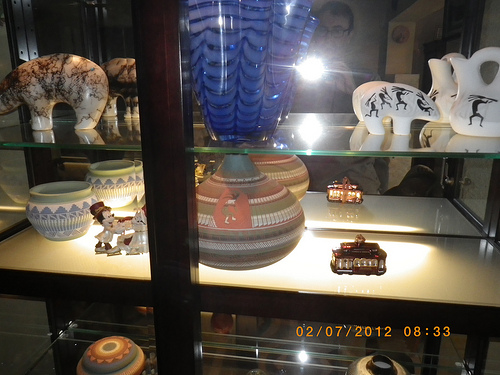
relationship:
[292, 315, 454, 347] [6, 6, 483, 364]
date of photo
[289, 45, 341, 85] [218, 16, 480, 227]
flash in mirror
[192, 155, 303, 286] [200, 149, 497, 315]
pottery in cabinet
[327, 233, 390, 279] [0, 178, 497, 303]
trolley toy on shelf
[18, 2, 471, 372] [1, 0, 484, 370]
wall supporting cabinet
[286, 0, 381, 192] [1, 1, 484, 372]
man reflected in glass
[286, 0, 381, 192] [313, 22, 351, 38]
man wearing glasses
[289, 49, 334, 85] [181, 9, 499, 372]
flash on glass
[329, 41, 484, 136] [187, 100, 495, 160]
items on shelf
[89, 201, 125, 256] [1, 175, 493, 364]
mickey mouse on hutch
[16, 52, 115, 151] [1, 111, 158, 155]
bear on hutch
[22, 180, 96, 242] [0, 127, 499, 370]
bowl on hutch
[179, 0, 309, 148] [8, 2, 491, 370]
glass on hutch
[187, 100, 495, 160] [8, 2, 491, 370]
shelf in hutch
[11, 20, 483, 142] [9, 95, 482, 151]
objects on shelf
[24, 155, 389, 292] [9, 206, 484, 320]
objects on shelf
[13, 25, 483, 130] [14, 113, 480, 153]
objects on shelf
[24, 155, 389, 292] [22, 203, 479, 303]
objects on shelf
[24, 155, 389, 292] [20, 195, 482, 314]
objects on shelf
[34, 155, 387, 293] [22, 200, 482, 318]
objects on shlef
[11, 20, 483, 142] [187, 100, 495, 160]
objects on shelf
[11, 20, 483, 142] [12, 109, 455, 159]
objects on shelf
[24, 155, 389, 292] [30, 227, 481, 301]
objects on shelf